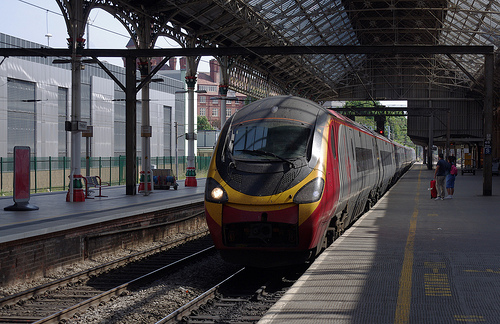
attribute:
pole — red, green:
[58, 52, 85, 204]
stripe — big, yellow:
[387, 167, 423, 322]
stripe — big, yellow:
[395, 164, 427, 322]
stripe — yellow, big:
[385, 166, 425, 322]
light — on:
[209, 182, 225, 200]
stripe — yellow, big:
[390, 162, 422, 322]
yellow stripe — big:
[386, 207, 416, 322]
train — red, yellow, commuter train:
[192, 91, 422, 278]